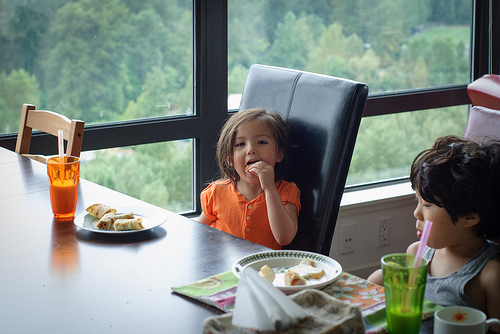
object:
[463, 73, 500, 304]
children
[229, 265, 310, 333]
napkin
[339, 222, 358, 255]
outlet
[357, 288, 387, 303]
flower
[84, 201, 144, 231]
food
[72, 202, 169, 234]
plate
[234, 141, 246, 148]
eye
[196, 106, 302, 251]
girl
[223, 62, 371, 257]
chair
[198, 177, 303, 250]
shirt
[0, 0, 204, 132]
window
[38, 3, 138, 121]
tree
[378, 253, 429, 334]
cup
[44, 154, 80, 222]
cup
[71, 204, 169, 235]
dish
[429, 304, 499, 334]
cup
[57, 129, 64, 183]
straw